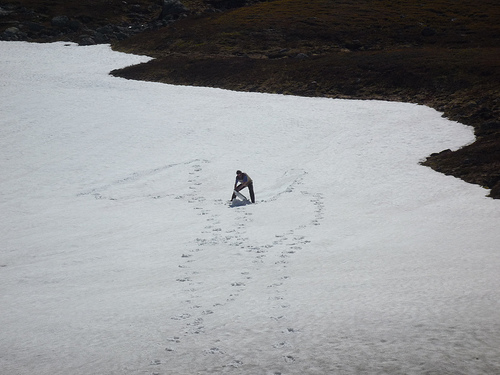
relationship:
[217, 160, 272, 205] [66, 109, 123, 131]
man in snow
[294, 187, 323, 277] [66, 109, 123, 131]
tracks in snow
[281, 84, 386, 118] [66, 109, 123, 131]
edge of snow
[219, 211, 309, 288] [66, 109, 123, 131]
tracks in snow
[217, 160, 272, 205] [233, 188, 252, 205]
man by skis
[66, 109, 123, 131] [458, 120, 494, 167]
snow on mountain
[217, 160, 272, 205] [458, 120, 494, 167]
man coming down mountain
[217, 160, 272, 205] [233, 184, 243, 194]
man has leg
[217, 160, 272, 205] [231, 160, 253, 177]
man wears cap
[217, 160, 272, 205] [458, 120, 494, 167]
man climbing mountain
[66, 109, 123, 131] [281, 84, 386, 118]
snow on edge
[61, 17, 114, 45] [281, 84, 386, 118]
boulders on edge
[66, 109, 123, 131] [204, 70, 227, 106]
snow meets dirt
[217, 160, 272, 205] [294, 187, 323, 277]
man making tracks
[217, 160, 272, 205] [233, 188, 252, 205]
man putting on skis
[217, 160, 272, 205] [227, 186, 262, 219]
man holding skis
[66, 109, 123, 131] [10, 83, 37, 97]
snow on ground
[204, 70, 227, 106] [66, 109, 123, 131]
dirt without snow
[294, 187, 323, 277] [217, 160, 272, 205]
tracks behind man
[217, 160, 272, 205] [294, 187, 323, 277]
man made tracks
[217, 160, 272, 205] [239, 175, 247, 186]
man wearing jacket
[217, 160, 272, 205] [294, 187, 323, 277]
man behind tracks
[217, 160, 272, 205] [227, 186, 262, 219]
man with skis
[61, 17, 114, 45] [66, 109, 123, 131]
boulders behind snow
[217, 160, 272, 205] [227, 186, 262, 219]
man has skis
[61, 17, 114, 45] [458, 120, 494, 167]
boulders on mountain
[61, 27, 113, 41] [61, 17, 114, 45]
boulders of boulders